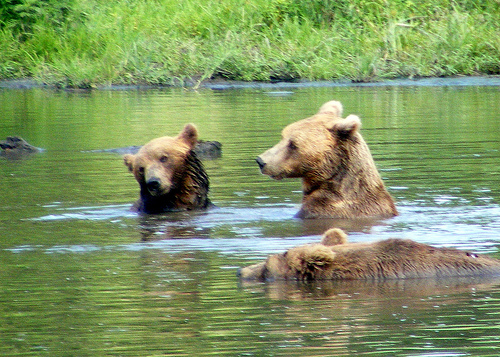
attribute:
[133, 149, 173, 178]
eyes — on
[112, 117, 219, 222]
bear — brown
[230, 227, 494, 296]
bear — brown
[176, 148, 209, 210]
spot — dark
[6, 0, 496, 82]
shrubs — small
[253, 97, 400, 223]
bear — light brown, brown, large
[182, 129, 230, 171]
rock — large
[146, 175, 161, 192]
nose — black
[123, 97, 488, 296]
bears — swimming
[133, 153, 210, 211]
fur — wet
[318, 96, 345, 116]
ears — on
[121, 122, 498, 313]
bears — brown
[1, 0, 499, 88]
bank line — grassy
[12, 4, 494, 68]
grass — green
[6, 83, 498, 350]
water — ripling, green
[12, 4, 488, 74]
foilage — green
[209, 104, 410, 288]
bear — brown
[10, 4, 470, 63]
shrubbery — green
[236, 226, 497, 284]
bear — brown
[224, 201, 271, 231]
sunlight — on